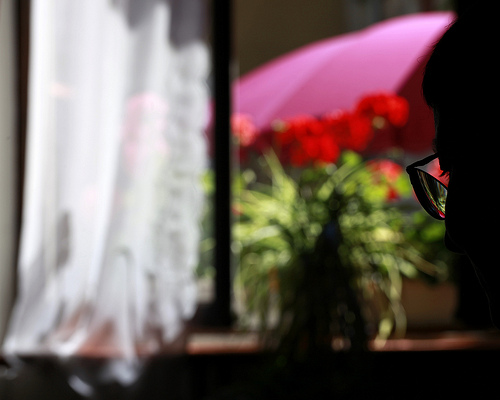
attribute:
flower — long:
[356, 93, 409, 285]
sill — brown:
[11, 332, 499, 362]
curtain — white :
[5, 2, 208, 389]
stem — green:
[359, 158, 456, 346]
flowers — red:
[243, 88, 450, 220]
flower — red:
[279, 95, 334, 188]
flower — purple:
[359, 84, 416, 126]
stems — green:
[240, 175, 427, 327]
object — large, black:
[290, 194, 366, 367]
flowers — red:
[187, 82, 444, 350]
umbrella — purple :
[212, 14, 497, 227]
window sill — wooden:
[7, 327, 484, 384]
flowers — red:
[239, 87, 409, 301]